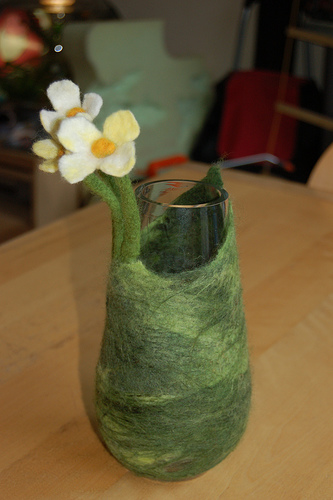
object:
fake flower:
[58, 108, 140, 183]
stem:
[109, 174, 139, 260]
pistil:
[92, 136, 117, 159]